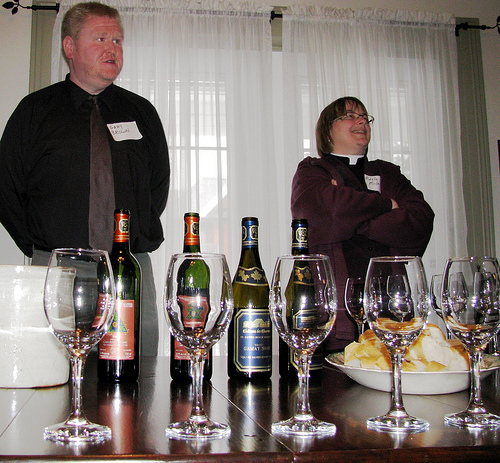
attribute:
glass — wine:
[53, 245, 109, 452]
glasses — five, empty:
[34, 248, 499, 447]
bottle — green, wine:
[231, 212, 276, 381]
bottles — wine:
[95, 210, 328, 383]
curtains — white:
[135, 13, 412, 197]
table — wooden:
[9, 373, 490, 457]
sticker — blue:
[237, 309, 284, 372]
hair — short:
[57, 8, 81, 31]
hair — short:
[313, 110, 335, 155]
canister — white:
[6, 263, 71, 395]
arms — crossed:
[316, 197, 436, 250]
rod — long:
[138, 5, 499, 39]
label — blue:
[238, 312, 270, 341]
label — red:
[100, 297, 138, 357]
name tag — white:
[108, 126, 145, 148]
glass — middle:
[266, 248, 343, 444]